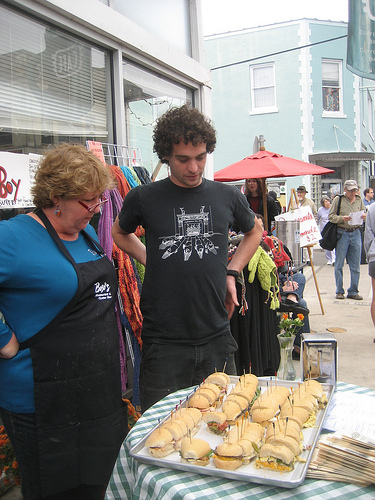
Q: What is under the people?
A: Sandwiches.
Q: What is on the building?
A: Windows.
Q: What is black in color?
A: The shirt.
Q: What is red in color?
A: Umbrella.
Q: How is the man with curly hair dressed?
A: T-shirt and jeans.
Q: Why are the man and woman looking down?
A: Looking at sandwiches.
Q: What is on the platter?
A: Sandiches.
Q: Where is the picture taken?
A: Outdoor market.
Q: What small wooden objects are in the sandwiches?
A: Toothpicks.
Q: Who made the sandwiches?
A: Woman in apron.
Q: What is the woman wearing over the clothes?
A: Apron.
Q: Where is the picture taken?
A: Outside some stores.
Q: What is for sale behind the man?
A: Scarves.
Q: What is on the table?
A: A tray.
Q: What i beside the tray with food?
A: Napkin holder.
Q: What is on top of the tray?
A: Sandwiches.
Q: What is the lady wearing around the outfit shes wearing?
A: An apron.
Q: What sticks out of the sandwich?
A: A tooth pick.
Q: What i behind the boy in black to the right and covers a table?
A: A umbrella.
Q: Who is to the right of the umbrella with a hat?
A: A man.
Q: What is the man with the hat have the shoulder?
A: A backpack.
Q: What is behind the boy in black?
A: A scarf stand.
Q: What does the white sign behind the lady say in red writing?
A: Boy.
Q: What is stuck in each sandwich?
A: A toothpick.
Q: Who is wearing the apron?
A: The woman in blue.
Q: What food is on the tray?
A: Sandwiches.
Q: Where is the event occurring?
A: On the sidewalk.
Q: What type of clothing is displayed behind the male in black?
A: Scarves.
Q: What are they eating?
A: Sandwiches.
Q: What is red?
A: Umbrella.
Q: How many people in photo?
A: 8.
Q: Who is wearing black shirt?
A: Man up front.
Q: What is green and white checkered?
A: Tablecloth.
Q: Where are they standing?
A: Close to a table holding sandwiches.